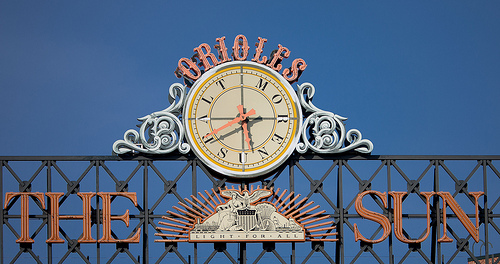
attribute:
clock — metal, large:
[173, 56, 308, 183]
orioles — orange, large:
[170, 27, 310, 84]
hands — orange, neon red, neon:
[202, 103, 260, 149]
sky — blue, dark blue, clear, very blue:
[3, 3, 496, 36]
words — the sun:
[2, 183, 487, 248]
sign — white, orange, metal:
[109, 25, 379, 179]